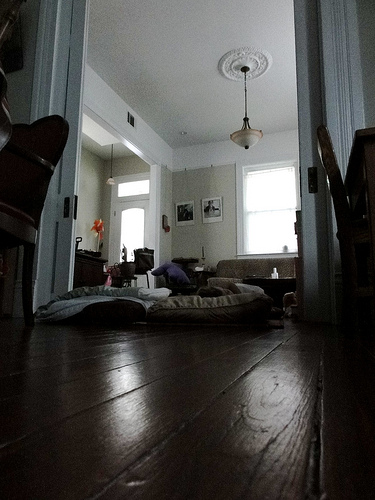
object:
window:
[240, 159, 302, 255]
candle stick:
[201, 256, 206, 269]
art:
[174, 199, 195, 226]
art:
[199, 194, 223, 223]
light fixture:
[215, 46, 274, 153]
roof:
[93, 7, 305, 147]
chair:
[153, 255, 199, 291]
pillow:
[33, 285, 172, 325]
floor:
[0, 317, 373, 498]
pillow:
[144, 290, 267, 320]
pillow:
[60, 281, 170, 296]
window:
[113, 177, 149, 198]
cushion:
[152, 288, 267, 318]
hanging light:
[108, 145, 121, 188]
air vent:
[123, 107, 141, 130]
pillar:
[85, 72, 189, 165]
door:
[112, 201, 145, 287]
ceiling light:
[222, 118, 285, 147]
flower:
[87, 216, 104, 252]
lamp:
[229, 64, 265, 152]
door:
[290, 0, 327, 335]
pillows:
[35, 283, 278, 319]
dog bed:
[38, 283, 268, 330]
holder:
[175, 243, 216, 273]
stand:
[96, 231, 100, 251]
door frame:
[72, 106, 155, 288]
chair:
[2, 74, 73, 334]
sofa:
[209, 257, 297, 291]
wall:
[0, 0, 375, 258]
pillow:
[153, 259, 189, 282]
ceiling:
[86, 1, 298, 148]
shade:
[231, 126, 264, 149]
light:
[104, 175, 116, 186]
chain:
[108, 145, 114, 179]